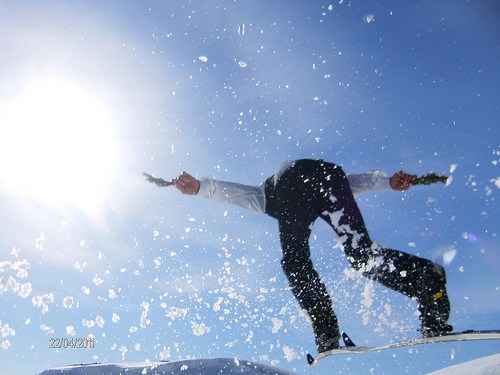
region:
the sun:
[16, 77, 110, 199]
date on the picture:
[46, 335, 103, 357]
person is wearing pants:
[276, 187, 418, 317]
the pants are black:
[280, 185, 389, 317]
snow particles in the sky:
[6, 256, 156, 336]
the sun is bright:
[2, 87, 125, 207]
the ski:
[318, 330, 498, 368]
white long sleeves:
[201, 173, 258, 210]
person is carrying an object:
[138, 168, 178, 189]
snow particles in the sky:
[193, 50, 268, 74]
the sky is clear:
[184, 35, 305, 125]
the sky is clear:
[201, 300, 253, 351]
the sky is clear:
[350, 309, 406, 336]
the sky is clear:
[192, 133, 239, 165]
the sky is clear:
[353, 77, 425, 130]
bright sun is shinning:
[18, 86, 135, 218]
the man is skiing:
[152, 111, 472, 353]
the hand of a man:
[137, 148, 260, 228]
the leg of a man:
[273, 208, 335, 343]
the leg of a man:
[330, 196, 474, 357]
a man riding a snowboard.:
[129, 140, 476, 362]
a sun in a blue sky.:
[1, 25, 171, 238]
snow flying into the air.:
[440, 233, 464, 274]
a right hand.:
[380, 151, 468, 203]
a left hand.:
[171, 168, 208, 194]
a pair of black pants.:
[276, 165, 472, 355]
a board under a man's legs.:
[271, 296, 483, 371]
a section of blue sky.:
[380, 50, 481, 108]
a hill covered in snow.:
[46, 331, 286, 371]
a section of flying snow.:
[99, 260, 271, 345]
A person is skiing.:
[186, 125, 471, 362]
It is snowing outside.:
[53, 188, 294, 338]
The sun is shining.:
[18, 84, 98, 189]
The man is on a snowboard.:
[270, 301, 497, 348]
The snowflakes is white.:
[61, 230, 226, 327]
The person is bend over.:
[146, 144, 449, 226]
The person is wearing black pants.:
[273, 160, 434, 337]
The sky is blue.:
[76, 31, 421, 124]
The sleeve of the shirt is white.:
[190, 161, 267, 208]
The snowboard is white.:
[333, 313, 491, 360]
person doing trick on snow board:
[135, 146, 475, 351]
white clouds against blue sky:
[21, 26, 136, 87]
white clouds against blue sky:
[25, 100, 108, 157]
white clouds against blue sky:
[10, 183, 137, 261]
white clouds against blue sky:
[26, 265, 159, 353]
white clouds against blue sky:
[141, 254, 255, 336]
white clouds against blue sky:
[134, 14, 253, 69]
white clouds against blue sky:
[263, 12, 392, 70]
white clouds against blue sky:
[284, 76, 418, 140]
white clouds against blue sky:
[358, 27, 446, 138]